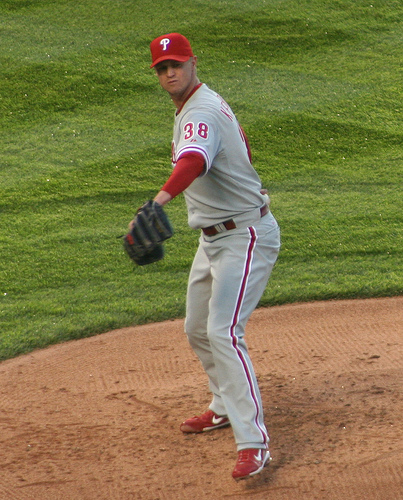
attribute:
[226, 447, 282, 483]
shoe — red, white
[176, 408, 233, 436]
shoe — red, white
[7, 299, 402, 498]
mound — dirt, red, dirty, brown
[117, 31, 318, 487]
pitcher — male, prepared, throwing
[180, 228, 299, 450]
pants — gray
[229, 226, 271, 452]
stripe — red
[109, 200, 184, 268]
glove — black, left handed, extended, large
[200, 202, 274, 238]
belt — brown, red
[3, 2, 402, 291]
grass — green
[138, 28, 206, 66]
cap — red, baseball cap, white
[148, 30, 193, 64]
hat — red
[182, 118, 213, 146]
number — 38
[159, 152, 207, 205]
shirt — red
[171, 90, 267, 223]
jersey — gray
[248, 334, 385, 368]
track — dirt